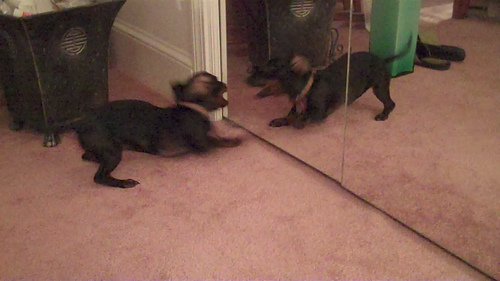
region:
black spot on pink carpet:
[81, 180, 203, 215]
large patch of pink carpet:
[49, 180, 333, 241]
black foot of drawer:
[27, 120, 71, 152]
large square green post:
[372, 15, 429, 75]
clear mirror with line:
[319, 111, 496, 198]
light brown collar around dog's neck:
[176, 96, 213, 117]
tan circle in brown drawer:
[51, 14, 97, 64]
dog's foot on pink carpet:
[100, 156, 163, 203]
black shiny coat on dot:
[115, 104, 192, 132]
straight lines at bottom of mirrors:
[282, 150, 434, 221]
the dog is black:
[101, 105, 268, 155]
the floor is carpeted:
[181, 192, 277, 238]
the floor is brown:
[213, 187, 292, 230]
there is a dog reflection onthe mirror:
[273, 55, 386, 125]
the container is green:
[373, 17, 420, 77]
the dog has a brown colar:
[173, 100, 215, 119]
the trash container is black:
[18, 40, 125, 109]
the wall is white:
[140, 20, 191, 70]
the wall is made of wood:
[145, 28, 190, 64]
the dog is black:
[76, 90, 194, 165]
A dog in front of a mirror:
[19, 54, 261, 196]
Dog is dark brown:
[19, 57, 271, 205]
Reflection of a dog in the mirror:
[236, 30, 436, 145]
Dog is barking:
[20, 65, 262, 196]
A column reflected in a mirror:
[359, 0, 431, 77]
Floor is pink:
[3, 57, 490, 279]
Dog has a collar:
[167, 96, 224, 126]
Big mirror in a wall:
[216, 0, 498, 280]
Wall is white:
[116, 0, 231, 111]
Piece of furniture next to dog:
[0, 5, 131, 132]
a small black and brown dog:
[25, 51, 263, 188]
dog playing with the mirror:
[47, 49, 432, 181]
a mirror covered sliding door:
[237, 0, 472, 271]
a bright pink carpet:
[9, 170, 394, 272]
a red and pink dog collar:
[175, 91, 215, 127]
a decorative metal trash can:
[1, 4, 121, 121]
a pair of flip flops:
[394, 16, 471, 87]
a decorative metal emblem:
[54, 10, 89, 57]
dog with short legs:
[79, 72, 246, 217]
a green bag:
[369, 0, 429, 87]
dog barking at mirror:
[31, 71, 266, 191]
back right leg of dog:
[78, 129, 146, 196]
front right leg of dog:
[185, 121, 217, 160]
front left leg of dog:
[214, 132, 247, 146]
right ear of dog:
[180, 73, 216, 95]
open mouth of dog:
[216, 79, 230, 109]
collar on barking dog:
[173, 93, 214, 120]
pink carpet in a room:
[1, 69, 477, 276]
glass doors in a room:
[219, 3, 498, 218]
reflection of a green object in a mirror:
[353, 3, 431, 82]